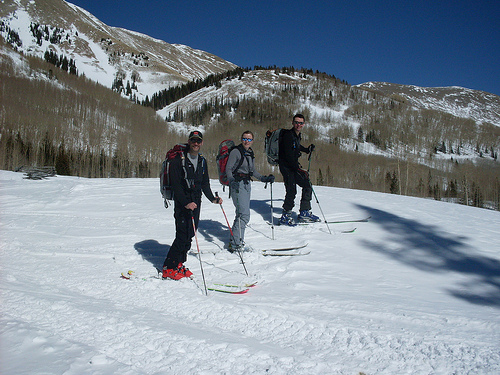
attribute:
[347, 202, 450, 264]
shadow —  tree 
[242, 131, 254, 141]
lens —  blue 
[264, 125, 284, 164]
pack —  grey  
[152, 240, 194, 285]
boots — red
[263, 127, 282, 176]
backpack — black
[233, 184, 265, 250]
pants — grey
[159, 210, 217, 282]
pants — black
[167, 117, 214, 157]
cap — black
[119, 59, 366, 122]
trees — tall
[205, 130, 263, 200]
jacket — grey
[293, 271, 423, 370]
snow — white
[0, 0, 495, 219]
range — snowy, mountain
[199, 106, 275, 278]
man — skiing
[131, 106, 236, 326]
man — preparing to ski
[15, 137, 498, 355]
snow — white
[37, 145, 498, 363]
snow — white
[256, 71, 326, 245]
man — preparing to ski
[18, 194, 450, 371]
snow — white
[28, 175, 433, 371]
snow — white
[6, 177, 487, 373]
snow — white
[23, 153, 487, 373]
snow — white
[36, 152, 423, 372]
snow — white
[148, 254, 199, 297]
snow boots — red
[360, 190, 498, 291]
shadow — of a tree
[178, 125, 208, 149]
cap — a ball cap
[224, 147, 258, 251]
outfit — gray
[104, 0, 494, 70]
sky — bright blue, clear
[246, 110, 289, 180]
backpack — gray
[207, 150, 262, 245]
outfit — grey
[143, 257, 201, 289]
skiboots — red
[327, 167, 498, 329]
tree — pine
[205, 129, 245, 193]
backpack — red, gray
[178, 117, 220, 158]
hat — black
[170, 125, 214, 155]
decal — red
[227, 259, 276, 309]
ski tips — red